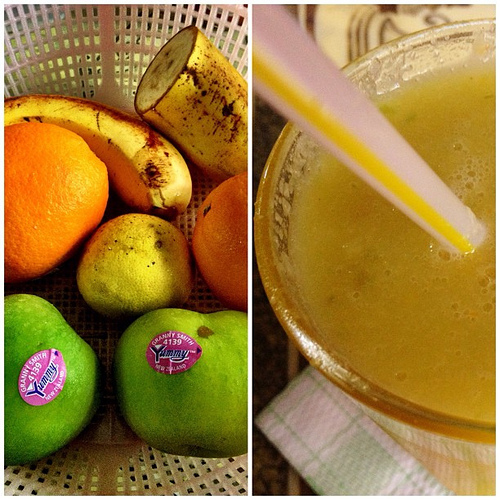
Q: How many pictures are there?
A: Two.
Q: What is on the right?
A: A drink.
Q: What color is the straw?
A: Yellow and white.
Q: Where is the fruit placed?
A: In a plastic bowl.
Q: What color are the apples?
A: Green.